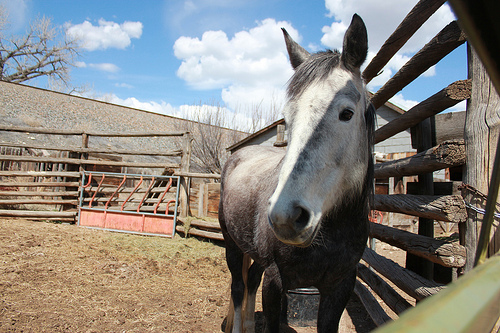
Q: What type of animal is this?
A: A horse.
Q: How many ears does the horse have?
A: Two.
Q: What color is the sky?
A: Blue.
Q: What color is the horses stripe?
A: White.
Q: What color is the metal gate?
A: Red.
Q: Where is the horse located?
A: The farm.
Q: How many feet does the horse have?
A: Four.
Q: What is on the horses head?
A: Hair.